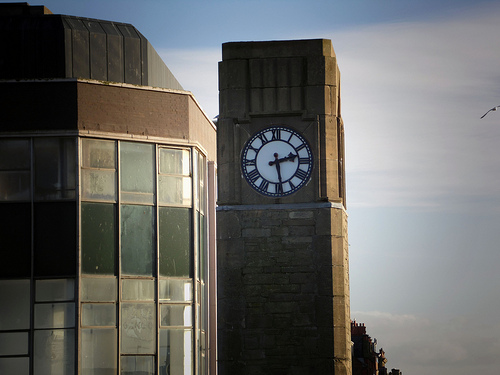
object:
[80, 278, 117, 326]
windows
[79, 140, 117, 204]
windows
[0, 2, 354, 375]
building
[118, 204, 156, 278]
windows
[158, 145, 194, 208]
windows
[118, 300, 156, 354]
windows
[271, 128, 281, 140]
numeral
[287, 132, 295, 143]
numeral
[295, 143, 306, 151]
numeral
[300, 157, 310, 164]
numeral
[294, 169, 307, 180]
numeral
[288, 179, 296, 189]
numeral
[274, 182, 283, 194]
numeral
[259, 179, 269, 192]
numeral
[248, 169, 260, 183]
numeral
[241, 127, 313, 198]
clock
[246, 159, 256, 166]
numeral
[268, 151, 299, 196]
dials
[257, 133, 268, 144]
numerals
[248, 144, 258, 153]
numerals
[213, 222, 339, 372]
wall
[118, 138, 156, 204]
window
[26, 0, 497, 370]
sky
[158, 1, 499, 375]
clouds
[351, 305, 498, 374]
clouds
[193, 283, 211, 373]
windows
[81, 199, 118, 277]
windows